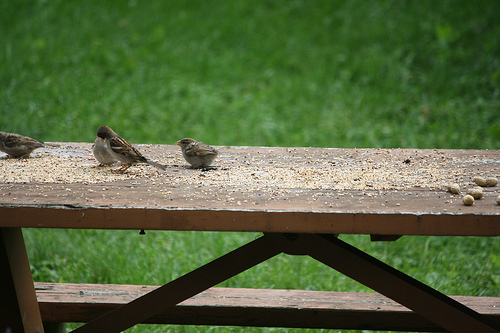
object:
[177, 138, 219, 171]
bird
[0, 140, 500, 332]
picnic table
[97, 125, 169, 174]
bird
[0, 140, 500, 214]
bird seed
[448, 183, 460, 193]
peanut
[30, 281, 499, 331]
bench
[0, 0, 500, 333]
lawn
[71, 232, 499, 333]
support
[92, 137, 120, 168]
bird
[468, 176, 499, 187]
peanut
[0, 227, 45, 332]
leg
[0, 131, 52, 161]
bird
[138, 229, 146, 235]
nail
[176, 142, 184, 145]
beak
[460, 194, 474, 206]
peanut